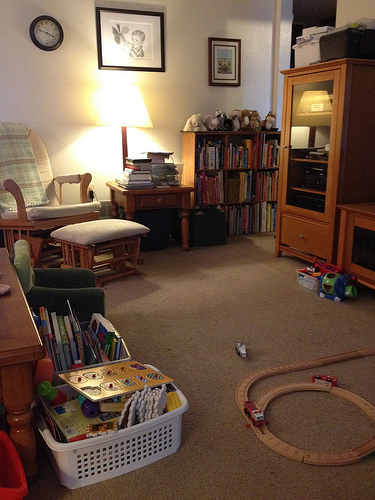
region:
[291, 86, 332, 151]
lamp reflection in glass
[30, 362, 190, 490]
white laundry basket full of kids stuff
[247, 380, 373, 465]
loop on a brown track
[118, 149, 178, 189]
stacks of books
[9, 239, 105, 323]
small green kids chair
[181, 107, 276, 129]
various stuffed animals sitting on shelf.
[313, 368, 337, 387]
red toy car on its side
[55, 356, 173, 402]
puzzle with red knobs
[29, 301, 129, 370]
books in a bin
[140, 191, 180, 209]
brown drawer on end table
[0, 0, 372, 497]
The photo of a living room.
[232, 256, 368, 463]
Toys on the floor.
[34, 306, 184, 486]
A white basket full of items for children.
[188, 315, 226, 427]
The brown Berber carpet.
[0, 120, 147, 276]
A chair and ottoman.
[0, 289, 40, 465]
A shiny brown wooden table.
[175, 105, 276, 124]
A collection of stuffed animals.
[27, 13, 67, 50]
A clock on the wall.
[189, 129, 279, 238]
A small wooden bookcase.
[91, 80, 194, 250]
The lamp on the end table.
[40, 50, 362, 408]
family room with books and toys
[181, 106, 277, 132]
stuffed animal toys on top of shelf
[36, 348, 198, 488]
white plastic basket filled with toys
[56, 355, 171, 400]
wooden puzzle on top of pile of toys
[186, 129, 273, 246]
shelf full of books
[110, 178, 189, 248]
small light brown wooden table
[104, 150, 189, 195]
books are on top of small table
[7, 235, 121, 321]
child sized green easy chair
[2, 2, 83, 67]
clock on wall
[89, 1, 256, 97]
framed art on white wall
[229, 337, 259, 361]
white toy on carpet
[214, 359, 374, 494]
brown train tracks with train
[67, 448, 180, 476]
small square on white tub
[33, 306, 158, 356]
many books in book bin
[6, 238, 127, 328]
green sofa in room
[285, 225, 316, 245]
handle on brown door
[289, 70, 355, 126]
reflection of lamp in glass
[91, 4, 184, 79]
large black and white picture on wall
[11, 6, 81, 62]
black clock on wall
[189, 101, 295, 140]
stuffed animals on top of shelf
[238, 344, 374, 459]
train track on the floor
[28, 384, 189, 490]
white basket holding toys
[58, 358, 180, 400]
puzzle on top of basket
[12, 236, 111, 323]
small child's chair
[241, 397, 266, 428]
fire engine on a track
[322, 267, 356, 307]
green and blue child's toy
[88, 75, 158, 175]
lamp against the wall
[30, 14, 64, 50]
white clock with black frame on the wall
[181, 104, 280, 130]
stuffed animals lines up on a book case